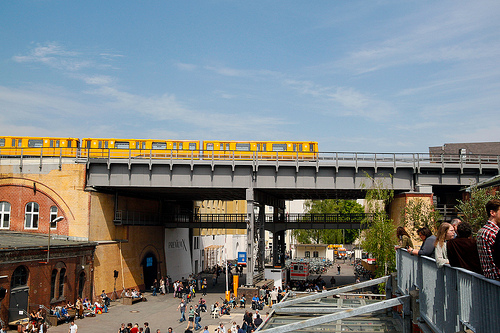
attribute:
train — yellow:
[0, 128, 321, 166]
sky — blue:
[1, 1, 499, 138]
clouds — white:
[1, 41, 495, 137]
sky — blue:
[9, 5, 167, 49]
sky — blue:
[8, 2, 393, 46]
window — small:
[111, 139, 130, 152]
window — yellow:
[290, 140, 297, 153]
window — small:
[261, 143, 267, 153]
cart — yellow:
[200, 136, 322, 167]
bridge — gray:
[83, 153, 404, 201]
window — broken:
[48, 200, 65, 228]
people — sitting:
[123, 285, 140, 299]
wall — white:
[163, 230, 196, 278]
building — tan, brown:
[1, 162, 171, 317]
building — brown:
[423, 136, 499, 159]